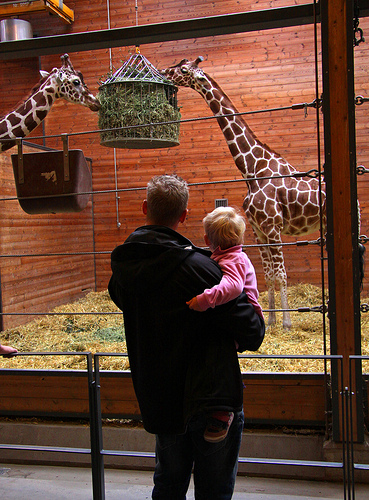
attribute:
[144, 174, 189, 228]
hair — blonde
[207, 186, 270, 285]
child — wearing pink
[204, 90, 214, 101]
spot — brown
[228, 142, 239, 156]
spot — brown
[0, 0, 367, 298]
wall — wooden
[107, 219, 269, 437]
jacket — black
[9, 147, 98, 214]
bucket — brown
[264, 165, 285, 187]
spot — brown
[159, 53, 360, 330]
giraffe — spot, brown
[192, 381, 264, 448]
shoes — pink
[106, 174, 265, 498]
man — in black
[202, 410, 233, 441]
shoe — pink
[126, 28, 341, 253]
giraffe — more visible , on the right 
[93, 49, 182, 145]
cage — hanging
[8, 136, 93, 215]
food container — brown